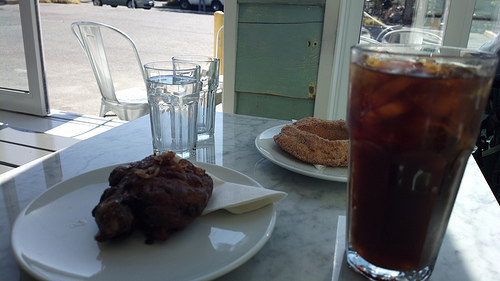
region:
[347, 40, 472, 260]
cold drink sitting on table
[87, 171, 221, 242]
food on white plate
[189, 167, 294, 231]
napkin on white plate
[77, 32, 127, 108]
white chair sitting outside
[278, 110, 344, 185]
fried food on white plate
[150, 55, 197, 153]
water glass on table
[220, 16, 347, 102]
green wall white frame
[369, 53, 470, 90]
ice in cold drink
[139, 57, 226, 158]
two glasses side by side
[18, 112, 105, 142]
floor leading outside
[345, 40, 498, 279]
a tall clear glass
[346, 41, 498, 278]
a glass of sweet tea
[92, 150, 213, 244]
a piece of meat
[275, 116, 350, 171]
a piece of fried catfish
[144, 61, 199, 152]
a short glass of water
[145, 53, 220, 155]
a pair of glasses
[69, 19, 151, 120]
a white plastic chair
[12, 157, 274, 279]
a white glass plate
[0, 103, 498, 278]
a marble table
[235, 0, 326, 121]
a green wall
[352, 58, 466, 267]
Dark soda in the glass.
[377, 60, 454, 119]
Ice in the glass.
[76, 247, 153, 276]
The plate is white.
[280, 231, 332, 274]
The table is marble.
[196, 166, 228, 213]
Napkin under the food.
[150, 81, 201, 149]
Water in the glass.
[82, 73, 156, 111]
The chair is white.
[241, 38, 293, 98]
The wall is green.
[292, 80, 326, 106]
Hole in the wall.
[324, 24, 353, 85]
The window frame is white.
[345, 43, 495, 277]
soda glass on the table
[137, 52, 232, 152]
water glasses on the table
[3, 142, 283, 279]
white plate with food on the table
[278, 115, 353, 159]
donut on plate on table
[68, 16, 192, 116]
white plastic chair outside the snack bar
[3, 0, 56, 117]
Open door at front of snack bar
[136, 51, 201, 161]
the glass is full of water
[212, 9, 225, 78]
yellow cement post outside the snack bar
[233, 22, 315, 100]
green is the color of the building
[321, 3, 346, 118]
white siding on the side of the building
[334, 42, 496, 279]
a glass filled with tea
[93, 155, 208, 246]
a piece of food on the table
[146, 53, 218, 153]
two small glasses of water on the table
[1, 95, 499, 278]
the table the food and drinks are on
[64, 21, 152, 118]
a chair sitting outside the restaurant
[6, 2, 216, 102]
part of the street for traffic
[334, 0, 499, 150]
a window of the restaurant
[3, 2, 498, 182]
the wall of the restaurant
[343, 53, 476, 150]
the ice cubes in the drink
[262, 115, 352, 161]
a big onion ring on the plate